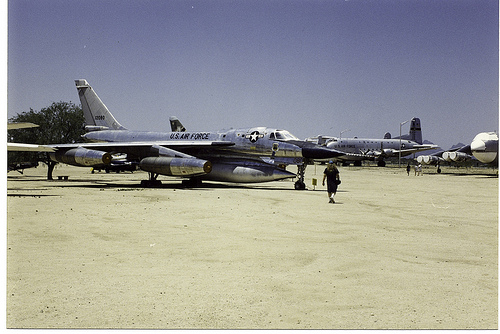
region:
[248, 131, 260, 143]
white star on black circle pattern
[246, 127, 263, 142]
white star on black circle pattern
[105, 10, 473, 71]
Sky is blue color.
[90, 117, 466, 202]
Jets are standing in ground.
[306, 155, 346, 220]
Woman is walking in ground.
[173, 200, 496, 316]
Ground in brown color.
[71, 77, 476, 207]
Jet is grey color.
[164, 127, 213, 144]
U.S air force is written in jet.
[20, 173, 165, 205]
Shadow falls on ground.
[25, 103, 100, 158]
Tree is behind the jet.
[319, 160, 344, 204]
Woman is wearing black dress.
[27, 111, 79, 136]
Leaves are green color.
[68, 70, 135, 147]
the tail of a plane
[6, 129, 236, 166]
the wing of a plane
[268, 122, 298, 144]
the cockpit of a plane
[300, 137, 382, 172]
the nose of a plane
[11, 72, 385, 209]
a gray metal plane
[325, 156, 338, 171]
the head of a person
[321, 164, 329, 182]
the arm of a person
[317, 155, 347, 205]
a person on the dirt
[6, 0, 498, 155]
a clear blue sky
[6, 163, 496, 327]
brown dirt on the ground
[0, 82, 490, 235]
An airfield with many aircraft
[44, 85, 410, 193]
An American fighter jet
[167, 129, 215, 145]
The plane says "U.S. AIR FORCE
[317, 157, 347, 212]
A man walking towards the jet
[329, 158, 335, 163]
The man wears a blue hat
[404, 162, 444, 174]
A group of people in the distance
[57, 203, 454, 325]
Dusty ground beneath the planes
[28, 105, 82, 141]
A tree behind the plane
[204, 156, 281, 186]
Missiles attached to the jet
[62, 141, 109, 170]
The jet's engine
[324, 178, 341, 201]
the legs of a person